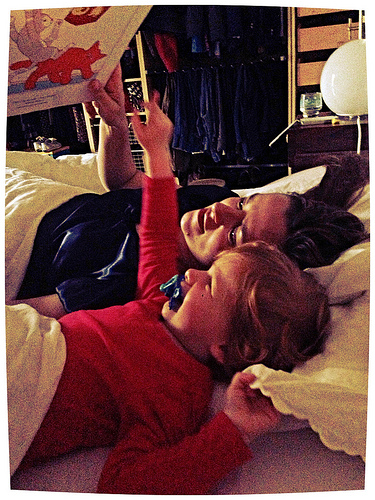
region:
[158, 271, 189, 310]
a pacifier in the child's mouth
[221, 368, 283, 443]
the hand of the child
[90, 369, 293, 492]
the arm of the child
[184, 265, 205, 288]
the nose of the child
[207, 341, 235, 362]
the ear of the child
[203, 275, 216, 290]
the eye of the child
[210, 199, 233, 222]
the nose of the woman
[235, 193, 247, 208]
the eye of the woman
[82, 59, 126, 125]
the hand of the woman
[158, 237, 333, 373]
the head of a child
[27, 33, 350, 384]
The two people are reading a book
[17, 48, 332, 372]
There is a woman and child in the bed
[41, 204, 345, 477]
The child has a pacifier in his mouth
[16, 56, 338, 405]
The child is pointing to the book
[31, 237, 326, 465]
The child is wearing a red shirt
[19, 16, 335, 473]
The picture was taken in a room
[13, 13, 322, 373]
The woman is holding a book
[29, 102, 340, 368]
The woman has dark hair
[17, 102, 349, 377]
The woman is wearing blue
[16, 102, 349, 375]
the bed covers are white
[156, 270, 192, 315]
a baby's pacifier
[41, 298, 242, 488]
a boy's long sleeve shirt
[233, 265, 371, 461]
a white pillow case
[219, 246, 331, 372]
a child's red hair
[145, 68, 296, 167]
blue clothes hanging in a closet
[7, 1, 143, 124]
a child's storybook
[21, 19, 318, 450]
a mom reading to a child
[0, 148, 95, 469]
a white blanket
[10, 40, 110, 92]
a story book character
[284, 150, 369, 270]
a woman's brown hair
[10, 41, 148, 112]
Reading a bedtime story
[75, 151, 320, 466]
Small child having a book read to him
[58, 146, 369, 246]
Mom reading a book to the child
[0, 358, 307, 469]
Child laying in bed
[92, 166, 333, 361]
Laying in bed with a book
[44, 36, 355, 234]
Reading before bed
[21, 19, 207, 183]
Reading in bed with your child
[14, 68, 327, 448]
Mother and child in the bed reading a story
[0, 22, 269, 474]
Story time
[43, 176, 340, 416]
Nighttime with the little one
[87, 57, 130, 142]
Mom's hand holding book.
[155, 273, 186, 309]
Child's blue pacifier.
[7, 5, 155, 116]
Storybook held overhead, reading.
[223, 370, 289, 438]
Child's hand holding pillowcase.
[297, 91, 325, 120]
Glass with something in it.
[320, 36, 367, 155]
Round lampshade on thin base.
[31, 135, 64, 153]
Child's sneakers ready to put on.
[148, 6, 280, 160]
Clothes in closet.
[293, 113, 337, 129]
Remote for Wii game.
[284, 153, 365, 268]
Mom's dark brown hair.